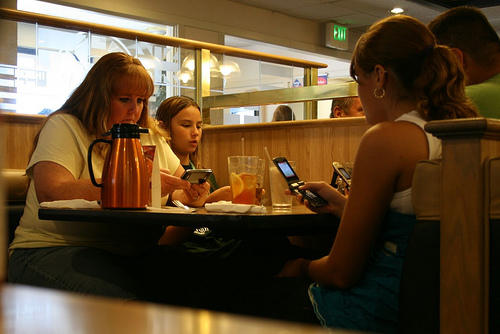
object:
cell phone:
[179, 169, 212, 185]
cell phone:
[272, 157, 330, 209]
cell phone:
[332, 161, 351, 186]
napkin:
[205, 200, 266, 213]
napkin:
[38, 198, 102, 209]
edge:
[37, 207, 319, 224]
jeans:
[305, 279, 397, 333]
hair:
[154, 95, 215, 195]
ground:
[425, 147, 442, 164]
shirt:
[10, 111, 185, 251]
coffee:
[87, 122, 156, 210]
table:
[36, 202, 333, 233]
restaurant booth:
[0, 113, 499, 334]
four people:
[5, 8, 500, 333]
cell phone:
[171, 164, 223, 191]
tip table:
[89, 218, 165, 290]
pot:
[86, 121, 157, 210]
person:
[154, 94, 265, 282]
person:
[299, 16, 499, 333]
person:
[417, 6, 499, 113]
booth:
[0, 0, 490, 327]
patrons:
[271, 79, 365, 123]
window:
[0, 3, 177, 122]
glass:
[228, 154, 265, 208]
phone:
[272, 157, 328, 208]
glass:
[24, 30, 94, 80]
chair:
[423, 117, 499, 331]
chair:
[0, 113, 51, 248]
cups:
[226, 155, 298, 209]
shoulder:
[369, 116, 499, 226]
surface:
[2, 282, 337, 333]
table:
[0, 262, 350, 332]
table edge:
[38, 208, 316, 225]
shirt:
[462, 74, 499, 119]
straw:
[240, 137, 245, 173]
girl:
[156, 95, 266, 203]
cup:
[227, 156, 266, 206]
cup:
[267, 159, 298, 210]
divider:
[0, 0, 330, 127]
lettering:
[333, 25, 346, 42]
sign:
[326, 20, 350, 51]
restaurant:
[0, 0, 497, 334]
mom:
[9, 51, 210, 309]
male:
[424, 8, 500, 122]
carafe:
[87, 122, 158, 211]